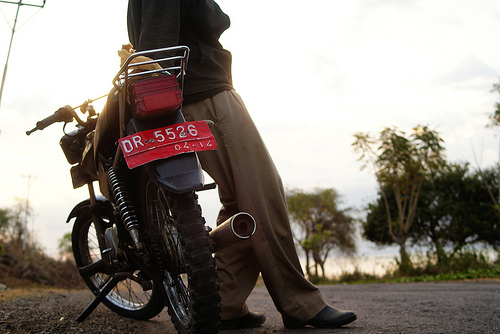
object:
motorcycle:
[24, 44, 259, 333]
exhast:
[209, 211, 258, 255]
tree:
[350, 122, 451, 280]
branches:
[349, 121, 449, 243]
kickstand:
[73, 269, 139, 325]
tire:
[140, 160, 220, 333]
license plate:
[117, 121, 218, 170]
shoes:
[224, 307, 360, 333]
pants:
[181, 87, 328, 330]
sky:
[2, 0, 499, 280]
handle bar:
[26, 104, 90, 135]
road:
[2, 281, 499, 333]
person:
[128, 0, 358, 333]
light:
[144, 91, 181, 110]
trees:
[361, 164, 500, 275]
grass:
[313, 266, 500, 285]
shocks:
[105, 165, 143, 253]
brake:
[34, 113, 61, 130]